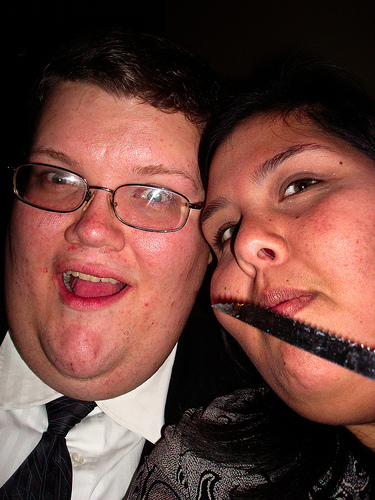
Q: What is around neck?
A: Tie.